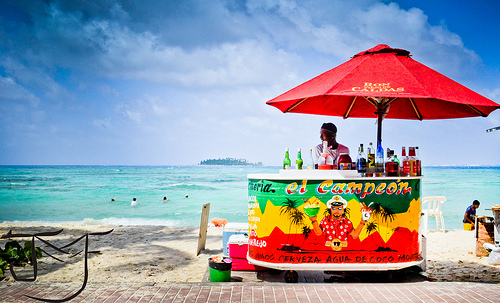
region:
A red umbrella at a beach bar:
[278, 36, 482, 130]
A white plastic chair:
[419, 181, 449, 228]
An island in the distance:
[191, 152, 259, 172]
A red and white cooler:
[225, 231, 255, 261]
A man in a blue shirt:
[460, 195, 476, 230]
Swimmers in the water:
[107, 185, 195, 207]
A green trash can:
[205, 247, 242, 285]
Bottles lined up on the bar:
[314, 123, 432, 170]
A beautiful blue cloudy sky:
[18, 5, 220, 116]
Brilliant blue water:
[29, 169, 101, 202]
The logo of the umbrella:
[331, 57, 416, 99]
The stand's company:
[246, 172, 425, 286]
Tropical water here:
[10, 155, 274, 247]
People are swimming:
[89, 164, 220, 215]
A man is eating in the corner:
[435, 165, 499, 262]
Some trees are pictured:
[3, 210, 117, 302]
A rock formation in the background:
[164, 117, 287, 188]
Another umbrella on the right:
[458, 108, 498, 138]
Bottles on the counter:
[253, 136, 438, 193]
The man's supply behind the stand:
[208, 188, 259, 288]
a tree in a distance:
[196, 157, 204, 164]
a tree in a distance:
[207, 157, 212, 165]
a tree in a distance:
[211, 157, 216, 166]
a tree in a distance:
[216, 155, 225, 165]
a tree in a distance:
[226, 155, 233, 169]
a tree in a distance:
[232, 155, 236, 162]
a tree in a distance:
[241, 157, 243, 162]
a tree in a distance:
[246, 161, 253, 168]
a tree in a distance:
[198, 158, 203, 163]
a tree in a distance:
[215, 153, 219, 165]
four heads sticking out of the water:
[105, 194, 191, 201]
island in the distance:
[202, 160, 261, 167]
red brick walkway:
[2, 280, 499, 300]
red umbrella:
[267, 47, 497, 117]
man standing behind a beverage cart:
[317, 122, 351, 167]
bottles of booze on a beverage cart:
[279, 143, 425, 177]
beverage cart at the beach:
[250, 45, 499, 285]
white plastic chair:
[422, 195, 446, 228]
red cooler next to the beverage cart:
[227, 236, 254, 268]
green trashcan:
[206, 256, 231, 281]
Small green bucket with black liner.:
[189, 247, 248, 295]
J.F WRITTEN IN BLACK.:
[3, 202, 123, 302]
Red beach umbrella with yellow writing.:
[280, 52, 470, 124]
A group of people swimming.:
[43, 170, 205, 208]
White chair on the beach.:
[421, 185, 456, 247]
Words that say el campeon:
[270, 177, 418, 198]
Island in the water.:
[172, 138, 261, 179]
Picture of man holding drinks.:
[273, 193, 403, 255]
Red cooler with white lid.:
[230, 227, 249, 286]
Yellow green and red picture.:
[246, 189, 418, 261]